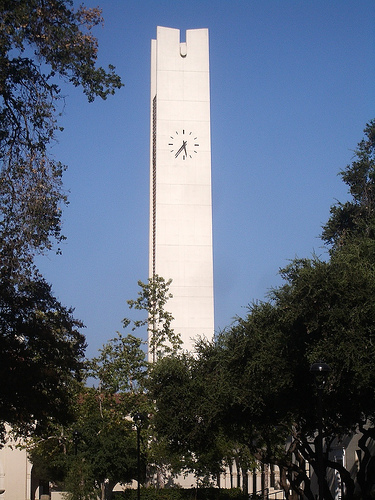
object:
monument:
[146, 22, 216, 493]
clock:
[166, 127, 201, 156]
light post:
[136, 407, 142, 488]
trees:
[157, 342, 225, 489]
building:
[327, 418, 375, 499]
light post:
[317, 358, 325, 491]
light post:
[75, 429, 78, 499]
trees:
[64, 406, 155, 500]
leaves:
[109, 77, 125, 90]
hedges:
[113, 487, 243, 500]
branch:
[259, 423, 312, 468]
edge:
[213, 481, 240, 493]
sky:
[0, 0, 375, 392]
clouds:
[87, 333, 101, 343]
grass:
[150, 487, 197, 497]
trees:
[127, 285, 372, 500]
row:
[140, 360, 371, 488]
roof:
[65, 382, 136, 412]